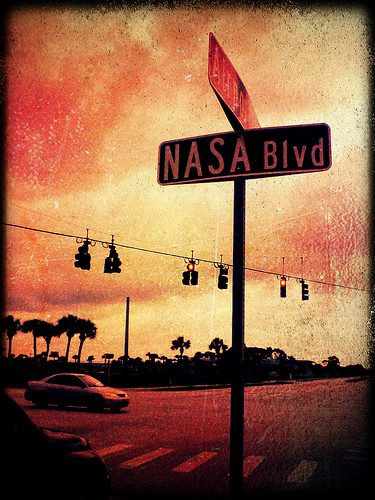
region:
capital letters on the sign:
[149, 121, 265, 194]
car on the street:
[10, 350, 148, 440]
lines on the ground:
[130, 426, 223, 491]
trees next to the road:
[12, 303, 104, 353]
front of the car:
[91, 379, 136, 418]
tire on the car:
[81, 390, 111, 417]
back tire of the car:
[24, 382, 61, 415]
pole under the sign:
[200, 195, 273, 369]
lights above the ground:
[258, 251, 332, 311]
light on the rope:
[270, 272, 293, 303]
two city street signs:
[141, 27, 338, 422]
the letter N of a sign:
[158, 141, 181, 177]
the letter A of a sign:
[181, 139, 201, 177]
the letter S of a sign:
[204, 135, 226, 174]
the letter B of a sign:
[259, 135, 279, 169]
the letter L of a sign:
[281, 138, 289, 172]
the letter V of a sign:
[290, 141, 307, 169]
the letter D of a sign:
[308, 133, 324, 167]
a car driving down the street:
[19, 369, 142, 415]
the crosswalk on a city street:
[89, 438, 372, 493]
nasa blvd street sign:
[135, 119, 371, 214]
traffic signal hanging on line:
[72, 237, 91, 282]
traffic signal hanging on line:
[105, 245, 147, 287]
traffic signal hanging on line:
[183, 266, 196, 292]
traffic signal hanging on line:
[216, 261, 230, 292]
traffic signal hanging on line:
[276, 258, 288, 308]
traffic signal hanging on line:
[298, 280, 316, 306]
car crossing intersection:
[9, 351, 155, 438]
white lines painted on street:
[137, 423, 210, 488]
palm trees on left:
[10, 316, 103, 354]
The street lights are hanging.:
[72, 235, 315, 304]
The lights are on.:
[179, 262, 286, 285]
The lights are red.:
[187, 261, 286, 288]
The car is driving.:
[17, 368, 130, 410]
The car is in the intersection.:
[23, 364, 130, 411]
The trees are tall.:
[3, 304, 99, 369]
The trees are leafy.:
[1, 312, 108, 359]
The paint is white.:
[83, 431, 319, 489]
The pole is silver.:
[228, 194, 249, 492]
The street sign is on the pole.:
[153, 120, 342, 185]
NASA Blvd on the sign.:
[141, 133, 329, 175]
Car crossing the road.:
[16, 361, 127, 429]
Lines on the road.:
[86, 434, 347, 492]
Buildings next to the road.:
[254, 348, 318, 383]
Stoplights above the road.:
[65, 228, 322, 319]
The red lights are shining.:
[178, 256, 294, 305]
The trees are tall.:
[4, 307, 90, 364]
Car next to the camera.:
[4, 381, 113, 496]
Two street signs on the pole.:
[139, 21, 341, 202]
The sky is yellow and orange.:
[23, 3, 368, 319]